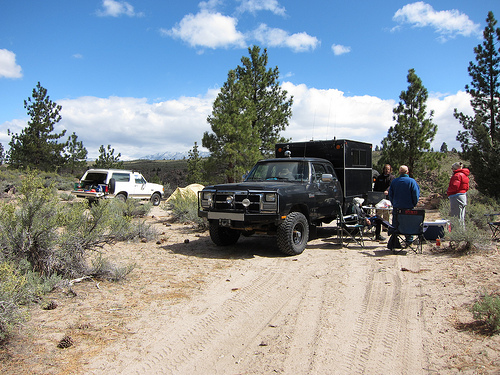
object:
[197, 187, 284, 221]
rack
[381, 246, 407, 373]
tracks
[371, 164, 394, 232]
people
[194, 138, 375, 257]
truck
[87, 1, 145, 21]
clouds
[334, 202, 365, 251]
camping chairs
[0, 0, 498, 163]
sky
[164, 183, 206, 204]
tent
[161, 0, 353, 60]
clouds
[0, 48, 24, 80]
clouds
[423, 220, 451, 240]
cooler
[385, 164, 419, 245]
man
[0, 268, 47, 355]
bushes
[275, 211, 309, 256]
tire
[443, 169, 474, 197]
coats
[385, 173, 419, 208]
coats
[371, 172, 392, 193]
coats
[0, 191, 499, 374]
ground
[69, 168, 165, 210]
truck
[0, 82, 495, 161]
white clouds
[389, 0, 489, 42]
white clouds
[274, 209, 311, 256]
wheel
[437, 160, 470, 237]
woman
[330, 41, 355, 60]
clouds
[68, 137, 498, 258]
site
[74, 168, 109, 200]
back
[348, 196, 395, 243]
woman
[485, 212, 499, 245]
chair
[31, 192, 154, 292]
dried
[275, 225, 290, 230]
tread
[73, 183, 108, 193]
stuff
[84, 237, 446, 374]
sand